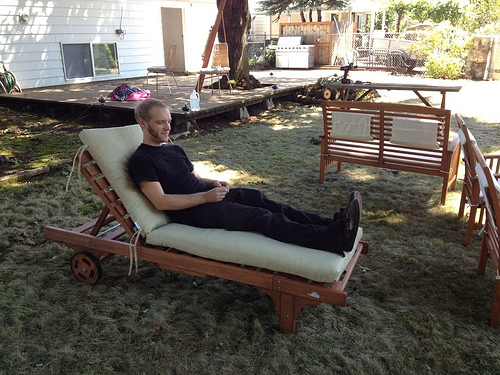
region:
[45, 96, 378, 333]
man wearing black laying on a wooden reclining lawn chair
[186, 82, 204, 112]
plastic bottle filled with clear liquid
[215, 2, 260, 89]
large brown tree trunk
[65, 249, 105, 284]
back wheel of wooden lawn chair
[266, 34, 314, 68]
outside barbecue grill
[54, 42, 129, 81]
2 windows on the house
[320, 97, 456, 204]
wooden bench with white cushions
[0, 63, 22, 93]
green garden hose on a spool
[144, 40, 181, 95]
brown and white chair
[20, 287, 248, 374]
ground covered in dried grass clippings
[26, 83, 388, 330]
The man is sitting on the chaise lounge.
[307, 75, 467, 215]
The bench is empty.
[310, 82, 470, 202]
The bench is made from wood.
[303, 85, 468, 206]
The bench is vacant.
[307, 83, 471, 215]
The bench is available.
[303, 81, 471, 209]
The bench is unoccupied.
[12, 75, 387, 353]
The chaise lounge has a padded cushion.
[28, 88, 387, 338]
The chaise lounge is in use.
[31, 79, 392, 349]
The chaise lounge is made from wood.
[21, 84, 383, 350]
The chaise lounge has wheels at the head of it.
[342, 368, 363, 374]
Wet side walk by a blue train.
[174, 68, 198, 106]
Wet side walk by a blue train.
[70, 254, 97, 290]
wheel on the chair.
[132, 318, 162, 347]
grass on the ground.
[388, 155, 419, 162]
bench made of wood.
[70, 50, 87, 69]
screen on the window.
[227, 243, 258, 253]
cushion on the chair.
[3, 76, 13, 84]
hose on the deck.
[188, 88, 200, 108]
jug on the deck.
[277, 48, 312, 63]
grill on the deck.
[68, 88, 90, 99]
deck near the house.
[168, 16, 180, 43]
doorway on the house.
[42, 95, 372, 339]
a man laying on a chair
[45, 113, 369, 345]
a brown wooden chair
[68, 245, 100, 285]
a wheel on a chair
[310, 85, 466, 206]
a brown wooden bench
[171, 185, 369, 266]
black pants on a man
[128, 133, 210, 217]
a black shirt on a man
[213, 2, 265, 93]
a large tree trunk coming through a deck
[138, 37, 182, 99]
a tan chair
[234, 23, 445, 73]
a chain link fence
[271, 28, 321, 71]
a bbq grill